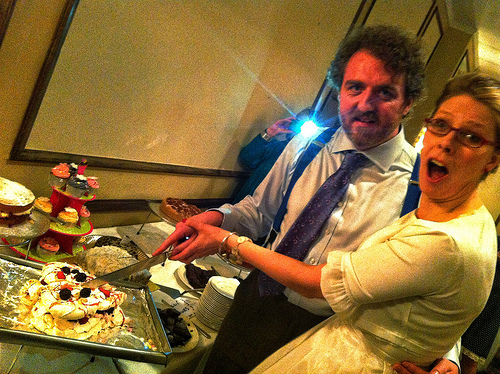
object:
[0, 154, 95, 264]
cupcakes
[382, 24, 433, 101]
curly hair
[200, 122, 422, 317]
shirt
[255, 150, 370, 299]
tie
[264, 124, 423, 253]
suspenders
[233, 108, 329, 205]
person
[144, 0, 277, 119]
flash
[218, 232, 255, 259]
bracelet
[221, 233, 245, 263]
wrist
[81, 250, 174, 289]
knife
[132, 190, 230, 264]
display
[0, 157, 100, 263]
display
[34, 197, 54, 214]
cupcake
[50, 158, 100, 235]
cupcake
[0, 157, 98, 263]
platter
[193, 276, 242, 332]
cup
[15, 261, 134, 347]
cake frosting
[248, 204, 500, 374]
dress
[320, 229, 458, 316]
long sleeve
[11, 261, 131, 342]
dessert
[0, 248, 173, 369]
sheet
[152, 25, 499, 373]
woman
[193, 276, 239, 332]
plates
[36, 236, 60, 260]
cupcake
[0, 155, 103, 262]
tower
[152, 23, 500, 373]
couple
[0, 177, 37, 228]
cake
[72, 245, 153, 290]
cake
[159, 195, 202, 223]
cake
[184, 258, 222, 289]
cake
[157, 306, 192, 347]
cake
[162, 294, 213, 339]
knife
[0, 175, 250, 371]
table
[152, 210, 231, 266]
hands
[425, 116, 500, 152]
glasses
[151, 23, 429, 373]
man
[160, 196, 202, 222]
pie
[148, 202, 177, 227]
tray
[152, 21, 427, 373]
guy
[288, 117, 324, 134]
camera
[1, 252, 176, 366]
foil pan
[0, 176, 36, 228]
layer cake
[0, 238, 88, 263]
tray stand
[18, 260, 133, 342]
cake